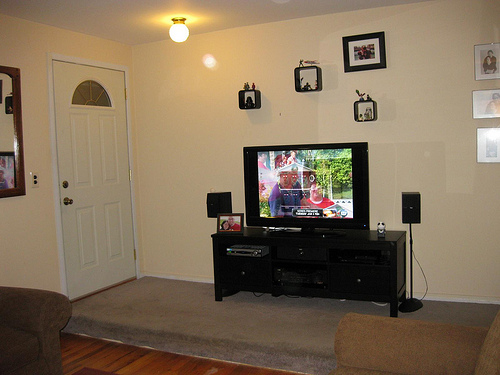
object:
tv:
[242, 142, 369, 234]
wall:
[133, 57, 190, 208]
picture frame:
[340, 31, 387, 74]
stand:
[210, 228, 407, 317]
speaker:
[397, 192, 423, 313]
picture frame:
[217, 213, 245, 234]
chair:
[0, 286, 72, 375]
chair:
[329, 313, 500, 373]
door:
[50, 59, 137, 304]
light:
[169, 17, 190, 42]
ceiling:
[1, 1, 414, 43]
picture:
[474, 43, 500, 80]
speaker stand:
[399, 224, 424, 314]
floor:
[60, 331, 190, 375]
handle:
[65, 198, 73, 205]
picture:
[472, 89, 499, 119]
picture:
[476, 126, 500, 162]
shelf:
[238, 90, 261, 110]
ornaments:
[245, 96, 254, 108]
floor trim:
[56, 278, 500, 375]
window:
[71, 80, 112, 108]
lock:
[63, 181, 69, 188]